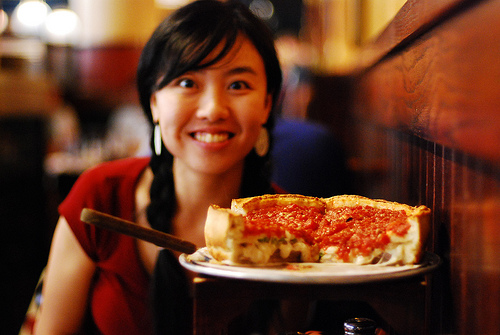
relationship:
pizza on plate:
[204, 190, 431, 268] [176, 243, 431, 283]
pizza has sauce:
[204, 190, 431, 268] [243, 203, 411, 256]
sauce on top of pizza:
[243, 203, 411, 256] [204, 190, 431, 268]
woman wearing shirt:
[32, 1, 294, 335] [57, 152, 298, 333]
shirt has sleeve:
[57, 152, 298, 333] [55, 156, 108, 262]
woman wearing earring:
[32, 1, 294, 335] [150, 121, 165, 161]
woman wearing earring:
[32, 1, 294, 335] [254, 121, 272, 157]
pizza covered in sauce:
[204, 190, 431, 268] [243, 203, 411, 256]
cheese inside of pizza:
[241, 236, 409, 269] [204, 190, 431, 268]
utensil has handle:
[77, 203, 291, 278] [75, 203, 200, 256]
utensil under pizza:
[77, 203, 291, 278] [204, 190, 431, 268]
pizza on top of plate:
[204, 190, 431, 268] [176, 243, 431, 283]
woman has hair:
[32, 1, 294, 335] [131, 5, 284, 334]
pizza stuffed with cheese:
[204, 190, 431, 268] [241, 236, 409, 269]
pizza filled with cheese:
[204, 190, 431, 268] [241, 236, 409, 269]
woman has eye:
[32, 1, 294, 335] [174, 73, 202, 93]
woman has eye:
[32, 1, 294, 335] [224, 75, 250, 97]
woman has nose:
[32, 1, 294, 335] [197, 83, 229, 126]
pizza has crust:
[204, 190, 431, 268] [200, 200, 243, 266]